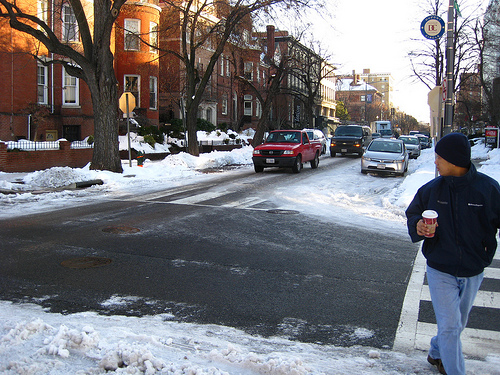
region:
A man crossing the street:
[393, 127, 498, 362]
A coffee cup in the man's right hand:
[406, 198, 448, 248]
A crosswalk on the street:
[395, 217, 499, 364]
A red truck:
[249, 122, 334, 178]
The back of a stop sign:
[108, 82, 150, 185]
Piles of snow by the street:
[2, 138, 274, 209]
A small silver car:
[355, 127, 415, 182]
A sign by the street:
[414, 12, 464, 144]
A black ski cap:
[425, 130, 480, 186]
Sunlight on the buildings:
[0, 0, 172, 95]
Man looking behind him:
[405, 132, 495, 366]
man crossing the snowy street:
[407, 133, 499, 347]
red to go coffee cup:
[419, 208, 441, 241]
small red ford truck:
[253, 128, 322, 174]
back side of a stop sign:
[115, 91, 140, 173]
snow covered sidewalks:
[6, 171, 126, 206]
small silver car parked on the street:
[360, 136, 408, 178]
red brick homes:
[111, 16, 268, 143]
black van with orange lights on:
[329, 123, 373, 159]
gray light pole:
[438, 13, 463, 134]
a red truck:
[226, 116, 326, 189]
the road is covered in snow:
[267, 113, 415, 273]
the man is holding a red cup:
[401, 124, 498, 365]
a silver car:
[355, 128, 412, 189]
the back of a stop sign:
[99, 83, 156, 182]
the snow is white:
[24, 293, 294, 371]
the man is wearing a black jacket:
[404, 153, 498, 284]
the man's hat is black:
[414, 116, 495, 196]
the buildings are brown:
[7, 5, 402, 186]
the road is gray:
[13, 166, 400, 351]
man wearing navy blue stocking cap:
[418, 127, 498, 187]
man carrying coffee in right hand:
[403, 199, 457, 253]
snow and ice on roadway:
[291, 178, 380, 236]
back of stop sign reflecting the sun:
[113, 80, 146, 177]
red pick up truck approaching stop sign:
[239, 119, 328, 174]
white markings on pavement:
[399, 255, 480, 360]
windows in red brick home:
[119, 1, 166, 83]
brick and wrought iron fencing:
[1, 137, 98, 162]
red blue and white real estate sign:
[480, 117, 497, 158]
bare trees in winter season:
[181, 2, 328, 112]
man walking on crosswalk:
[404, 133, 498, 368]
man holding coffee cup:
[402, 129, 499, 371]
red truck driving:
[248, 126, 321, 176]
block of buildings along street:
[2, 0, 385, 143]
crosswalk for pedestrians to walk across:
[395, 182, 491, 372]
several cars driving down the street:
[245, 105, 425, 180]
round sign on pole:
[416, 13, 446, 38]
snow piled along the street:
[3, 140, 248, 193]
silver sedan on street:
[357, 135, 407, 175]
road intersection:
[1, 149, 446, 374]